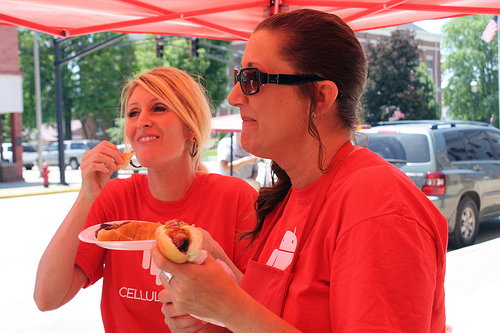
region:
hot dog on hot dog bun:
[147, 213, 214, 268]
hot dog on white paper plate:
[70, 202, 171, 253]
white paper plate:
[76, 210, 185, 260]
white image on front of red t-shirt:
[262, 218, 304, 273]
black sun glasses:
[215, 52, 326, 99]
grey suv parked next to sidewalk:
[347, 100, 497, 251]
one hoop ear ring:
[118, 142, 144, 177]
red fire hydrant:
[32, 156, 59, 193]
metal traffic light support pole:
[50, 33, 79, 186]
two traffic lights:
[142, 31, 208, 70]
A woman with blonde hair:
[66, 62, 248, 332]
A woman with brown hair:
[206, 6, 419, 330]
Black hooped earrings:
[119, 137, 202, 162]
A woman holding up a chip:
[20, 64, 244, 329]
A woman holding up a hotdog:
[164, 7, 454, 329]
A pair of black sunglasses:
[232, 62, 324, 92]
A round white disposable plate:
[76, 216, 171, 254]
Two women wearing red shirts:
[25, 9, 462, 331]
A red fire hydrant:
[34, 162, 55, 189]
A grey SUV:
[359, 114, 495, 248]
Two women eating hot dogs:
[55, 25, 425, 325]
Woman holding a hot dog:
[155, 210, 247, 326]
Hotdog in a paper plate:
[79, 201, 165, 257]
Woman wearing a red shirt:
[240, 125, 445, 327]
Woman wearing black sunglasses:
[222, 62, 326, 98]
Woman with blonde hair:
[112, 60, 215, 176]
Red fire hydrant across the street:
[35, 159, 50, 189]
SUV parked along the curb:
[350, 105, 497, 241]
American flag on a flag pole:
[472, 15, 497, 47]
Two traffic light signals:
[152, 37, 200, 67]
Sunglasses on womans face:
[217, 64, 324, 94]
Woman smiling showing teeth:
[133, 132, 165, 144]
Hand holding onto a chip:
[79, 141, 134, 196]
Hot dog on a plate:
[77, 214, 161, 246]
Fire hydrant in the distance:
[35, 158, 53, 188]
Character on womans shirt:
[264, 224, 301, 276]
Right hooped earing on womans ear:
[185, 138, 200, 159]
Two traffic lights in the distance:
[148, 29, 205, 62]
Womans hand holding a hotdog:
[150, 220, 230, 323]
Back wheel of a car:
[455, 189, 485, 247]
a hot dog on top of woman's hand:
[154, 215, 206, 262]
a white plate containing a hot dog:
[76, 216, 161, 247]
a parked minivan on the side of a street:
[355, 113, 499, 243]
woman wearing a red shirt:
[241, 139, 446, 331]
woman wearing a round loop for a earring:
[184, 134, 199, 157]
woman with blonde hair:
[118, 67, 210, 175]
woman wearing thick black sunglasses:
[232, 68, 324, 95]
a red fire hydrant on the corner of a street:
[39, 162, 49, 187]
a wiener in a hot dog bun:
[166, 225, 188, 250]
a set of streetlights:
[154, 35, 201, 61]